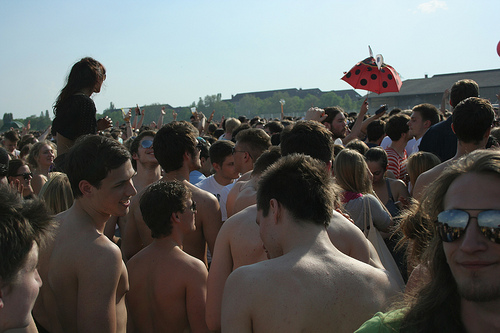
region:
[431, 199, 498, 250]
Reflective sunglasses on man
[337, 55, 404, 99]
Open umbrella to provide shade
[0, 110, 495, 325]
Crowd of people on warm day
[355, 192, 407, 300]
Bag over woman's shoulder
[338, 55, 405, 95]
Black polka dots on umbrella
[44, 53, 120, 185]
Woman sitting on man's shoulders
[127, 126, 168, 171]
Man looking up in sky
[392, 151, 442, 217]
Woman with a cigarette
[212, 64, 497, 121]
Buildings on hill in background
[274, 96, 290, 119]
Lamppost in background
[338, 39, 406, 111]
umbrella in the air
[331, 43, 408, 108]
umbrella is black and red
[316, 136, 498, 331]
man looking at camera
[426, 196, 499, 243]
man wearing mirrored sunglasses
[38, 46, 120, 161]
woman sitting on shoulders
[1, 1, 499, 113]
sky is clear and blue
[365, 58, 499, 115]
house in the distance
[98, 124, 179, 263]
man looking up to the sky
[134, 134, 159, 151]
man wearing pair of sunglasses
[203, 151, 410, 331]
man not wearing shirt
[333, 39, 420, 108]
red and black ladybug umbrella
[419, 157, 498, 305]
guy wearing aviator style shades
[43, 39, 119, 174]
girl sitting on someone's shoulders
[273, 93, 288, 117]
road sign in the distance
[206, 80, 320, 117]
buildings in the distance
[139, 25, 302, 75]
pale blue sky above the people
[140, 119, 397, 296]
a crowd of people outside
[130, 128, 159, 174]
person looking up wearing sunglasses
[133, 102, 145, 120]
bottle held up in the air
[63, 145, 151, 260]
guy looking to the side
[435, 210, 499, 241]
The man is wearing sunglasses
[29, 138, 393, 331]
The men are not wearing shirts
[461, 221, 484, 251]
The nose of the man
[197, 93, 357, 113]
Trees in the distance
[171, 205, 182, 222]
The right ear of the man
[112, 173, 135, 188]
The eyes of the man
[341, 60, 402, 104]
An umbrella in the crowd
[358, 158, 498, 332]
The man is smiling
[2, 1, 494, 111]
The sky above the group of people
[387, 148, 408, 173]
The person is wearing a striped shirt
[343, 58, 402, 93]
an umbrella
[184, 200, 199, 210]
eye glasses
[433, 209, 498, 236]
person is wearing sun glasses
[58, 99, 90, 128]
a person wearing a black shirt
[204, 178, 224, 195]
man wearing a white shirt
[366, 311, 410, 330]
person wearing a green shirt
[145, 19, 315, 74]
the sky is clear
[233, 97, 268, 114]
the bushes are green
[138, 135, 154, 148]
a man wearing sun glasses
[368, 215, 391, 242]
a women carrying a white bag